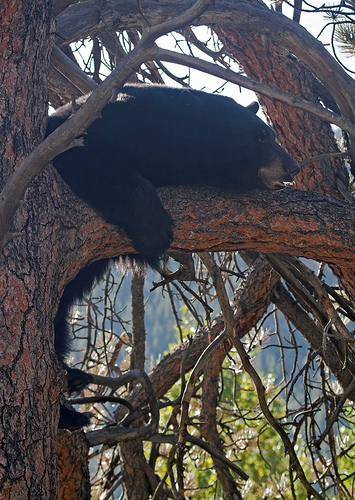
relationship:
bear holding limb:
[45, 83, 300, 430] [54, 171, 355, 293]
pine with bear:
[0, 0, 355, 500] [45, 83, 300, 430]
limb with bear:
[57, 176, 354, 292] [45, 83, 300, 430]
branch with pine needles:
[318, 1, 354, 75] [321, 2, 347, 23]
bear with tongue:
[45, 83, 300, 430] [270, 179, 286, 188]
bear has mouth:
[45, 83, 300, 430] [256, 166, 296, 190]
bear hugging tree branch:
[45, 83, 300, 430] [162, 184, 351, 260]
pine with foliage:
[0, 0, 355, 500] [227, 363, 259, 411]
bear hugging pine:
[45, 83, 300, 430] [0, 0, 355, 500]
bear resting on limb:
[45, 83, 300, 430] [45, 158, 353, 269]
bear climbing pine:
[45, 83, 300, 430] [0, 0, 355, 500]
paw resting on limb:
[130, 203, 174, 258] [170, 197, 348, 251]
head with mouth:
[199, 94, 302, 192] [256, 159, 297, 191]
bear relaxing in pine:
[45, 83, 300, 430] [11, 215, 350, 332]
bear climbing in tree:
[45, 83, 300, 430] [2, 1, 93, 495]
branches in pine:
[63, 271, 320, 491] [0, 0, 355, 500]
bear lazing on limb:
[41, 72, 311, 266] [55, 165, 353, 285]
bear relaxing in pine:
[45, 83, 300, 430] [0, 0, 355, 500]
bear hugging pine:
[45, 83, 300, 430] [0, 166, 353, 492]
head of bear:
[204, 94, 301, 194] [45, 83, 300, 430]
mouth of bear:
[249, 152, 302, 195] [41, 72, 311, 266]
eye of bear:
[258, 133, 266, 143] [45, 74, 299, 368]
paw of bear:
[130, 203, 175, 263] [45, 83, 300, 430]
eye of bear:
[254, 129, 270, 144] [45, 83, 300, 430]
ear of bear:
[247, 99, 261, 110] [45, 83, 300, 430]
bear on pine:
[45, 83, 300, 430] [0, 0, 355, 500]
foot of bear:
[64, 361, 92, 392] [38, 84, 318, 256]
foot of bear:
[57, 403, 91, 428] [38, 84, 318, 256]